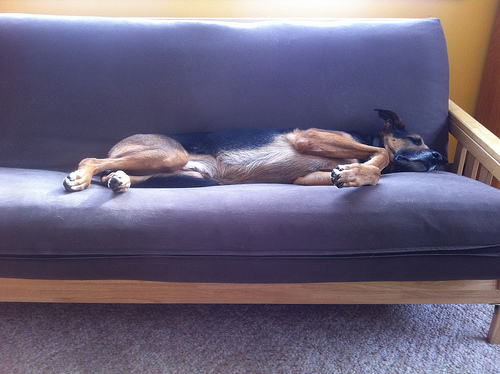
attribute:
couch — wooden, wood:
[0, 17, 499, 344]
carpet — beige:
[5, 292, 498, 369]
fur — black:
[198, 125, 259, 163]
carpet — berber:
[2, 300, 498, 370]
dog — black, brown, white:
[66, 106, 453, 210]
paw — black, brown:
[103, 168, 134, 199]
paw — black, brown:
[326, 158, 361, 189]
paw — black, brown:
[56, 163, 96, 194]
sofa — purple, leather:
[0, 10, 499, 347]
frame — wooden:
[1, 276, 496, 305]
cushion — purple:
[2, 12, 498, 279]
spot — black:
[162, 127, 277, 158]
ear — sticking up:
[373, 105, 408, 135]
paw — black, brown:
[64, 166, 89, 194]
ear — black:
[374, 105, 410, 130]